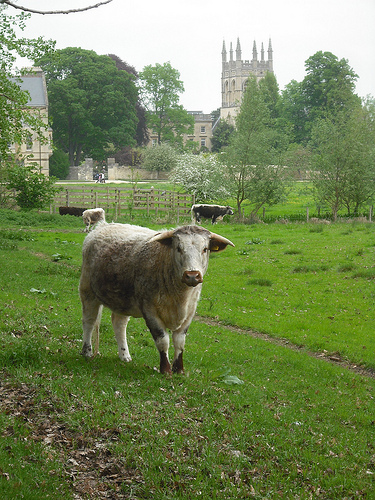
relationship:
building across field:
[144, 112, 211, 160] [4, 176, 371, 498]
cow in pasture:
[81, 206, 235, 374] [1, 183, 373, 496]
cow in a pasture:
[81, 206, 235, 374] [63, 377, 357, 494]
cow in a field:
[81, 206, 235, 374] [0, 179, 375, 499]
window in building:
[201, 121, 208, 135] [138, 105, 215, 151]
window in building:
[197, 134, 206, 151] [149, 117, 222, 153]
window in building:
[190, 136, 194, 142] [129, 108, 210, 156]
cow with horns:
[81, 215, 210, 373] [148, 229, 235, 254]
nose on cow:
[182, 260, 203, 288] [81, 215, 210, 373]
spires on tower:
[212, 35, 275, 69] [223, 41, 274, 126]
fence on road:
[74, 183, 180, 217] [77, 172, 158, 188]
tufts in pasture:
[240, 232, 362, 304] [240, 224, 364, 343]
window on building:
[40, 125, 54, 154] [15, 63, 54, 186]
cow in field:
[81, 206, 235, 374] [246, 228, 341, 383]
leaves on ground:
[19, 399, 53, 430] [4, 372, 179, 490]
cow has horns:
[81, 206, 235, 374] [142, 225, 238, 248]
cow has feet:
[81, 206, 235, 374] [156, 349, 185, 376]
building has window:
[144, 106, 219, 159] [198, 123, 207, 135]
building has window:
[144, 112, 211, 160] [198, 140, 206, 148]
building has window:
[0, 66, 55, 184] [229, 73, 240, 87]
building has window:
[0, 38, 288, 211] [228, 73, 236, 86]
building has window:
[0, 38, 288, 211] [223, 92, 236, 108]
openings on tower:
[221, 80, 239, 90] [221, 39, 275, 130]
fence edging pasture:
[0, 183, 194, 222] [1, 183, 373, 496]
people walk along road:
[94, 168, 106, 182] [0, 178, 148, 185]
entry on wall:
[91, 160, 110, 180] [62, 155, 171, 179]